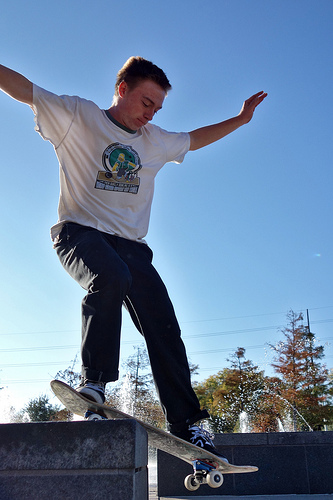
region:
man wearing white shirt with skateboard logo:
[28, 81, 194, 239]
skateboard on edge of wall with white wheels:
[47, 375, 263, 491]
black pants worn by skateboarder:
[49, 219, 213, 430]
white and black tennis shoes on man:
[70, 381, 219, 455]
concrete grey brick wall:
[1, 414, 157, 495]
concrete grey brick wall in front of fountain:
[156, 420, 331, 493]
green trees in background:
[14, 303, 331, 427]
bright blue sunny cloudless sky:
[5, 4, 331, 421]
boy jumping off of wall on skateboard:
[0, 49, 272, 491]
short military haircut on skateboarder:
[113, 53, 177, 91]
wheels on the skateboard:
[188, 473, 229, 490]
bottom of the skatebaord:
[141, 428, 197, 455]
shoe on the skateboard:
[175, 419, 214, 448]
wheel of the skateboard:
[83, 407, 111, 420]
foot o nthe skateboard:
[63, 377, 105, 404]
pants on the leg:
[80, 334, 115, 374]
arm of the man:
[167, 117, 233, 157]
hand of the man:
[239, 84, 281, 124]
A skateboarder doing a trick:
[5, 50, 280, 494]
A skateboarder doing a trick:
[8, 51, 268, 490]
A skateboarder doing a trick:
[4, 48, 269, 493]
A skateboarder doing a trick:
[4, 50, 275, 491]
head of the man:
[106, 51, 160, 124]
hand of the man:
[231, 77, 266, 123]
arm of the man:
[185, 113, 229, 146]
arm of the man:
[2, 77, 31, 105]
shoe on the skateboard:
[75, 376, 110, 400]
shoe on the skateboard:
[190, 430, 229, 458]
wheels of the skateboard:
[174, 473, 222, 492]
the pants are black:
[142, 293, 171, 344]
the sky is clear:
[1, 265, 66, 318]